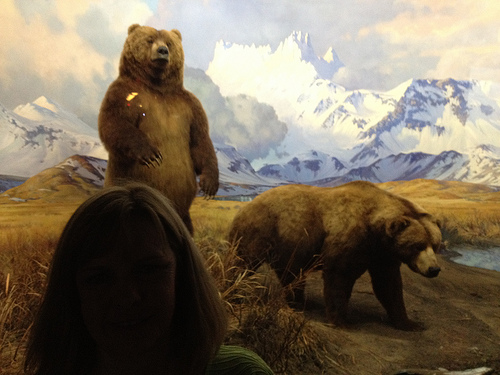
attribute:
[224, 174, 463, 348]
statues — large 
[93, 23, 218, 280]
bear — together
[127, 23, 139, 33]
ear — bear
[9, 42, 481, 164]
mountains — snowy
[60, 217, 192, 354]
hair — brown, should-length 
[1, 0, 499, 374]
exhibit — museum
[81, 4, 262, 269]
bear — brown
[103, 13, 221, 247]
bear — standing up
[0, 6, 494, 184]
mountain — snowy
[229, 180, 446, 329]
bear — brown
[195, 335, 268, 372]
shirt — green